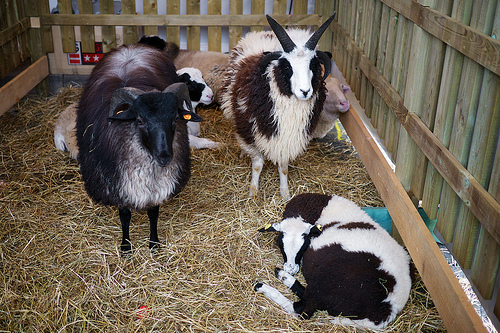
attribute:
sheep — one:
[242, 186, 420, 324]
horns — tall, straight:
[260, 7, 333, 56]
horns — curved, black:
[114, 78, 195, 119]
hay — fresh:
[30, 234, 106, 295]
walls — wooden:
[42, 0, 468, 158]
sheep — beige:
[317, 72, 357, 144]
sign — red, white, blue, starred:
[68, 42, 109, 65]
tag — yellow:
[176, 106, 200, 132]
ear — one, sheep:
[167, 92, 197, 120]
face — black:
[115, 93, 198, 166]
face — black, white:
[267, 49, 331, 101]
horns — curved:
[104, 76, 204, 120]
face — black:
[127, 90, 185, 169]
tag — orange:
[172, 106, 200, 129]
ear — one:
[175, 81, 201, 121]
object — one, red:
[120, 296, 159, 320]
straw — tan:
[20, 201, 121, 307]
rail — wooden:
[361, 120, 487, 328]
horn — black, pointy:
[263, 11, 296, 53]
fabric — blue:
[361, 201, 394, 233]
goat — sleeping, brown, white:
[252, 189, 413, 328]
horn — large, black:
[262, 13, 299, 50]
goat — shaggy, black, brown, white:
[71, 39, 199, 252]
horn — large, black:
[261, 8, 296, 52]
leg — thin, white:
[243, 154, 271, 201]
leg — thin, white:
[273, 161, 296, 205]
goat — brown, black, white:
[220, 11, 344, 202]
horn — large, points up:
[261, 14, 298, 54]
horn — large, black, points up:
[303, 11, 337, 52]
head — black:
[105, 79, 197, 163]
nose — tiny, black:
[300, 88, 311, 98]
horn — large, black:
[260, 11, 297, 56]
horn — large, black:
[305, 12, 332, 50]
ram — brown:
[73, 40, 200, 255]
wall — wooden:
[400, 12, 495, 204]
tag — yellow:
[259, 218, 270, 232]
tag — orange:
[182, 114, 192, 122]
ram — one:
[75, 32, 208, 239]